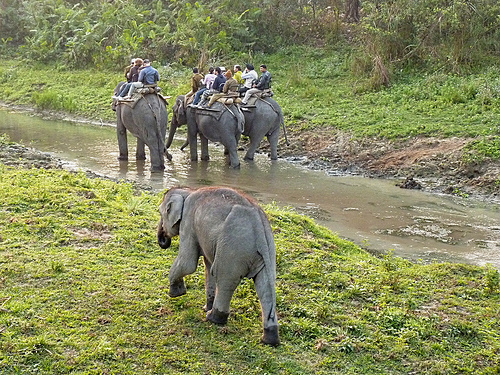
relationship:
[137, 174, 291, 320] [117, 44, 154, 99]
elephant following man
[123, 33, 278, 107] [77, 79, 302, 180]
people riding elephants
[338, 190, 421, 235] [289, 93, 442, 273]
lush with river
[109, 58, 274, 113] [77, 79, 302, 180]
tourists riding elephants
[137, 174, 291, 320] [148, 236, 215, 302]
elephant has feet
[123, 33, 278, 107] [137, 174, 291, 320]
people riding elephant